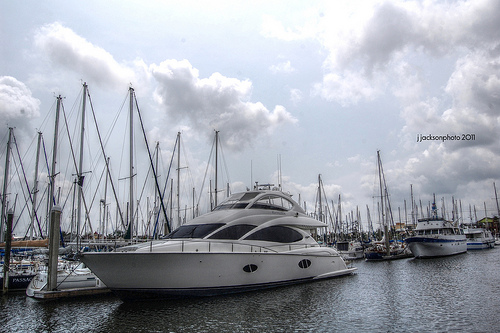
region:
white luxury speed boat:
[76, 181, 358, 295]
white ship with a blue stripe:
[403, 203, 468, 259]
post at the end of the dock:
[46, 204, 61, 289]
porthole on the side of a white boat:
[240, 262, 258, 274]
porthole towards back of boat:
[295, 256, 315, 271]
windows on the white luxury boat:
[168, 223, 303, 243]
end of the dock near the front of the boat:
[24, 268, 109, 300]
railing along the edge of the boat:
[79, 236, 316, 255]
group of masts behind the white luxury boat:
[2, 79, 233, 234]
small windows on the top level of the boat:
[211, 190, 260, 207]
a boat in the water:
[59, 121, 428, 331]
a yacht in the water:
[24, 95, 390, 332]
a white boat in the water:
[55, 102, 390, 332]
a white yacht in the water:
[54, 129, 434, 330]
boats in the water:
[4, 64, 495, 305]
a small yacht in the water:
[62, 138, 419, 318]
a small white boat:
[44, 111, 381, 329]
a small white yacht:
[57, 97, 412, 330]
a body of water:
[384, 268, 485, 330]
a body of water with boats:
[0, 51, 497, 331]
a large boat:
[73, 155, 355, 298]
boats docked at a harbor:
[0, 45, 495, 300]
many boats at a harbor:
[0, 41, 495, 306]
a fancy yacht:
[60, 131, 385, 301]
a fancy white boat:
[62, 130, 382, 310]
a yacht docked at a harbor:
[50, 116, 392, 312]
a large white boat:
[37, 124, 408, 320]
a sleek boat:
[69, 138, 379, 322]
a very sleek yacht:
[62, 140, 374, 302]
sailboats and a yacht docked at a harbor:
[5, 70, 376, 322]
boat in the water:
[95, 178, 350, 298]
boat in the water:
[402, 213, 474, 262]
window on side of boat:
[262, 228, 290, 244]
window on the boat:
[432, 226, 442, 234]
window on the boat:
[170, 225, 204, 240]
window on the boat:
[226, 225, 243, 242]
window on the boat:
[421, 226, 432, 233]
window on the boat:
[414, 228, 419, 234]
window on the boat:
[473, 230, 478, 237]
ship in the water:
[101, 180, 358, 297]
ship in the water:
[406, 215, 470, 263]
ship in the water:
[468, 226, 494, 252]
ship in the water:
[371, 242, 410, 262]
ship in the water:
[344, 241, 362, 258]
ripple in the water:
[276, 310, 290, 323]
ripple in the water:
[315, 299, 330, 316]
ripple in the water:
[158, 311, 173, 322]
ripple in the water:
[105, 315, 118, 327]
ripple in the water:
[58, 317, 78, 330]